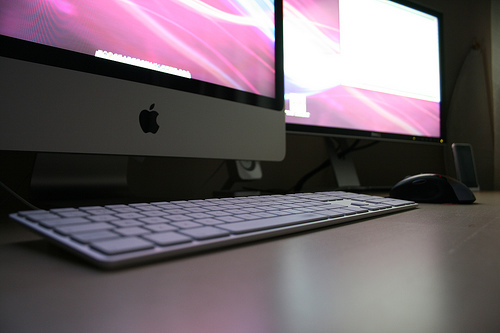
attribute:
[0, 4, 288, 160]
computer — on, apple, black, silver, silvertone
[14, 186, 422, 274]
keyboard — flat, white, raised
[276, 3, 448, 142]
screen — purple, white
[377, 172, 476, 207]
mouse — black, tan, nonnative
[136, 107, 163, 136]
apple — black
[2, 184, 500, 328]
desk — wooden, grey, large, brown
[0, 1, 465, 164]
screens — pink, identical, empty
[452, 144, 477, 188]
speakers — small, tiny